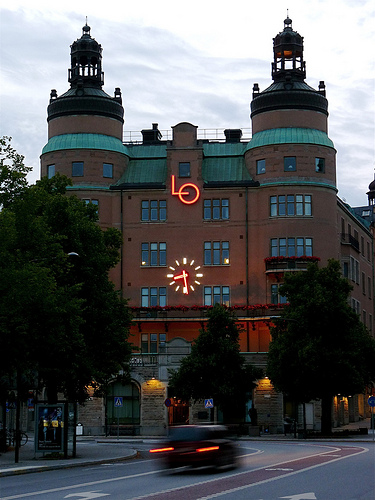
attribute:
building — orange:
[52, 35, 342, 418]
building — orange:
[44, 103, 360, 469]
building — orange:
[21, 60, 352, 484]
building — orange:
[42, 92, 359, 424]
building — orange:
[16, 65, 373, 433]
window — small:
[140, 199, 149, 224]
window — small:
[149, 196, 159, 229]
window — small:
[158, 195, 166, 226]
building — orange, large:
[21, 6, 372, 439]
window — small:
[201, 197, 212, 224]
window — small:
[220, 197, 228, 222]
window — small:
[252, 156, 269, 176]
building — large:
[43, 16, 368, 426]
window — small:
[281, 154, 297, 171]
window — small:
[313, 154, 328, 175]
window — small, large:
[174, 156, 195, 181]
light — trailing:
[193, 443, 219, 456]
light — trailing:
[151, 443, 175, 456]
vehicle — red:
[146, 418, 242, 472]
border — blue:
[34, 401, 42, 449]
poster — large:
[28, 394, 74, 458]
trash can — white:
[71, 417, 83, 438]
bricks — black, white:
[147, 399, 158, 407]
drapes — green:
[110, 391, 136, 420]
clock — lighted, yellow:
[163, 251, 201, 293]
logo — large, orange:
[168, 171, 199, 204]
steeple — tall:
[63, 17, 102, 88]